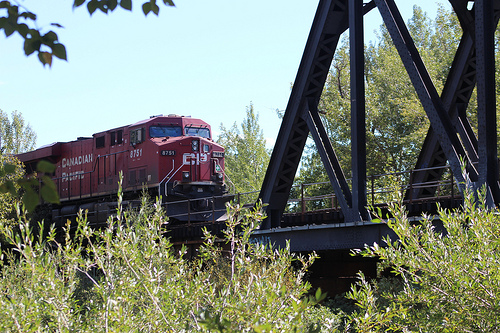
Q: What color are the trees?
A: Green.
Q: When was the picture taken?
A: Daytime.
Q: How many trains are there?
A: One.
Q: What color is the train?
A: Red and black.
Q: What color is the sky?
A: Blue.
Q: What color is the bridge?
A: Black.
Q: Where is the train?
A: On the tracks.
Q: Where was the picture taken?
A: At a railroad bridge.